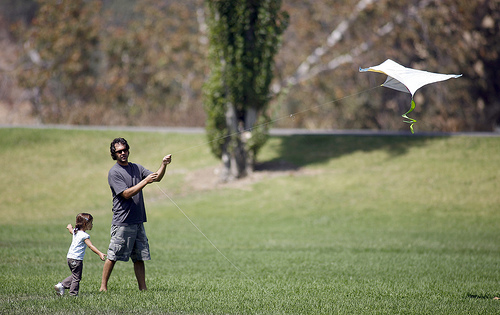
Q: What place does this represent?
A: It represents the park.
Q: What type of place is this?
A: It is a park.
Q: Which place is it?
A: It is a park.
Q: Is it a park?
A: Yes, it is a park.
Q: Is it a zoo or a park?
A: It is a park.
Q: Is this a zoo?
A: No, it is a park.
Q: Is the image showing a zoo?
A: No, the picture is showing a park.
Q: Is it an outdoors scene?
A: Yes, it is outdoors.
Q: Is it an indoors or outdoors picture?
A: It is outdoors.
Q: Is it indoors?
A: No, it is outdoors.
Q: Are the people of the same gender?
A: No, they are both male and female.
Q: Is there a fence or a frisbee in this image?
A: No, there are no fences or frisbees.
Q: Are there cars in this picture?
A: No, there are no cars.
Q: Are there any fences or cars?
A: No, there are no cars or fences.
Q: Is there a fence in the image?
A: No, there are no fences.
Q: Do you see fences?
A: No, there are no fences.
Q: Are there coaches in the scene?
A: No, there are no coaches.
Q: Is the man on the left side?
A: Yes, the man is on the left of the image.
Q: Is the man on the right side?
A: No, the man is on the left of the image.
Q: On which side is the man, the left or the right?
A: The man is on the left of the image.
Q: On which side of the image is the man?
A: The man is on the left of the image.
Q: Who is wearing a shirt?
A: The man is wearing a shirt.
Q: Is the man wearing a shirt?
A: Yes, the man is wearing a shirt.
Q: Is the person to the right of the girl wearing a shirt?
A: Yes, the man is wearing a shirt.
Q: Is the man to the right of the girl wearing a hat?
A: No, the man is wearing a shirt.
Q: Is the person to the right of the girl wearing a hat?
A: No, the man is wearing a shirt.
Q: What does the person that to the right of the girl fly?
A: The man flies the kite.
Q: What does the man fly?
A: The man flies the kite.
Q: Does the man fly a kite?
A: Yes, the man flies a kite.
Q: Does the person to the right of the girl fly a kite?
A: Yes, the man flies a kite.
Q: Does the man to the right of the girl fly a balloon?
A: No, the man flies a kite.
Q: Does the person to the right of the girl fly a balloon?
A: No, the man flies a kite.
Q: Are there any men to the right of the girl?
A: Yes, there is a man to the right of the girl.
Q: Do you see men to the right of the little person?
A: Yes, there is a man to the right of the girl.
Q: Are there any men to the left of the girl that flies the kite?
A: No, the man is to the right of the girl.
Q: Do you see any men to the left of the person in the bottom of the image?
A: No, the man is to the right of the girl.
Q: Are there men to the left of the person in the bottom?
A: No, the man is to the right of the girl.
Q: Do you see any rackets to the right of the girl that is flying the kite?
A: No, there is a man to the right of the girl.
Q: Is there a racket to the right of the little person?
A: No, there is a man to the right of the girl.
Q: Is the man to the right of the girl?
A: Yes, the man is to the right of the girl.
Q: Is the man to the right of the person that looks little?
A: Yes, the man is to the right of the girl.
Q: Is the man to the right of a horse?
A: No, the man is to the right of the girl.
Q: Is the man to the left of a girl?
A: No, the man is to the right of a girl.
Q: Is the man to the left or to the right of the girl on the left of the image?
A: The man is to the right of the girl.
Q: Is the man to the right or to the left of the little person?
A: The man is to the right of the girl.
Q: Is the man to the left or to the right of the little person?
A: The man is to the right of the girl.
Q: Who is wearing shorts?
A: The man is wearing shorts.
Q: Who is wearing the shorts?
A: The man is wearing shorts.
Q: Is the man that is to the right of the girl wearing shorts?
A: Yes, the man is wearing shorts.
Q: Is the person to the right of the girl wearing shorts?
A: Yes, the man is wearing shorts.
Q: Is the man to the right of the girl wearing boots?
A: No, the man is wearing shorts.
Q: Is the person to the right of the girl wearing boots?
A: No, the man is wearing shorts.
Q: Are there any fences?
A: No, there are no fences.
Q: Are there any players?
A: No, there are no players.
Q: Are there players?
A: No, there are no players.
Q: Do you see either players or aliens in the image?
A: No, there are no players or aliens.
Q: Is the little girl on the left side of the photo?
A: Yes, the girl is on the left of the image.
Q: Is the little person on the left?
A: Yes, the girl is on the left of the image.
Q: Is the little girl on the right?
A: No, the girl is on the left of the image.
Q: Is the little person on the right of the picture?
A: No, the girl is on the left of the image.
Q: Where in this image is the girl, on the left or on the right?
A: The girl is on the left of the image.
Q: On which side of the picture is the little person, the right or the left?
A: The girl is on the left of the image.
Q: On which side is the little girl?
A: The girl is on the left of the image.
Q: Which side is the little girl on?
A: The girl is on the left of the image.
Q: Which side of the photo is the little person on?
A: The girl is on the left of the image.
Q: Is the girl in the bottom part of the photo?
A: Yes, the girl is in the bottom of the image.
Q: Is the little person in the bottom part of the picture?
A: Yes, the girl is in the bottom of the image.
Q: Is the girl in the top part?
A: No, the girl is in the bottom of the image.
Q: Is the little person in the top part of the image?
A: No, the girl is in the bottom of the image.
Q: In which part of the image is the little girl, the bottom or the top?
A: The girl is in the bottom of the image.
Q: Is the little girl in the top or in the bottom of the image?
A: The girl is in the bottom of the image.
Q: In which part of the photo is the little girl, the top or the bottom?
A: The girl is in the bottom of the image.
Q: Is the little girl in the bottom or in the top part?
A: The girl is in the bottom of the image.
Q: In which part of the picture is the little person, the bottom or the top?
A: The girl is in the bottom of the image.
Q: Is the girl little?
A: Yes, the girl is little.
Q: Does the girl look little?
A: Yes, the girl is little.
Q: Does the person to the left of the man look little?
A: Yes, the girl is little.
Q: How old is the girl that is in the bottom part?
A: The girl is little.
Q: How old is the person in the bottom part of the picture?
A: The girl is little.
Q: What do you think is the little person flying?
A: The girl is flying the kite.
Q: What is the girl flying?
A: The girl is flying the kite.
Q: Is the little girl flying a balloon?
A: No, the girl is flying the kite.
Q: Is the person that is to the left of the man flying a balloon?
A: No, the girl is flying the kite.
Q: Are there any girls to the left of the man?
A: Yes, there is a girl to the left of the man.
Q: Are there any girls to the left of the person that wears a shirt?
A: Yes, there is a girl to the left of the man.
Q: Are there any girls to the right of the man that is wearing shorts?
A: No, the girl is to the left of the man.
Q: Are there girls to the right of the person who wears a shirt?
A: No, the girl is to the left of the man.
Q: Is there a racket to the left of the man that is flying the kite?
A: No, there is a girl to the left of the man.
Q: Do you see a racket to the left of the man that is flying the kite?
A: No, there is a girl to the left of the man.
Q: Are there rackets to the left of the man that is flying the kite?
A: No, there is a girl to the left of the man.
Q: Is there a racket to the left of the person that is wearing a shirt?
A: No, there is a girl to the left of the man.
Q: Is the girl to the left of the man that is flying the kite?
A: Yes, the girl is to the left of the man.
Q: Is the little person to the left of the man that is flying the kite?
A: Yes, the girl is to the left of the man.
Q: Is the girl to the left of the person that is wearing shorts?
A: Yes, the girl is to the left of the man.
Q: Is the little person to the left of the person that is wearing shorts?
A: Yes, the girl is to the left of the man.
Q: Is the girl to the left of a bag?
A: No, the girl is to the left of the man.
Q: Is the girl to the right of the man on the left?
A: No, the girl is to the left of the man.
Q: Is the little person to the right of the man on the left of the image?
A: No, the girl is to the left of the man.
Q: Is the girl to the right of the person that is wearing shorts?
A: No, the girl is to the left of the man.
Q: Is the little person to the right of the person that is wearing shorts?
A: No, the girl is to the left of the man.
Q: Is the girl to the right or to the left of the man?
A: The girl is to the left of the man.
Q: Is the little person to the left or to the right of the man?
A: The girl is to the left of the man.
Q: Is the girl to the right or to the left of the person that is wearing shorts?
A: The girl is to the left of the man.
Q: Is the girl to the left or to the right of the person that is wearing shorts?
A: The girl is to the left of the man.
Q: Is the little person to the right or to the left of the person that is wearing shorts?
A: The girl is to the left of the man.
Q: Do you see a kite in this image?
A: Yes, there is a kite.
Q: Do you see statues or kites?
A: Yes, there is a kite.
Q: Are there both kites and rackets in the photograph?
A: No, there is a kite but no rackets.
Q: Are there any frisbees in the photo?
A: No, there are no frisbees.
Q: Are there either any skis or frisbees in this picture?
A: No, there are no frisbees or skis.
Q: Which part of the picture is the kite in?
A: The kite is on the right of the image.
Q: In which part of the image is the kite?
A: The kite is on the right of the image.